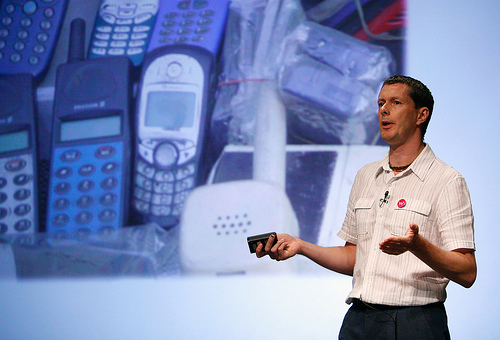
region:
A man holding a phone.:
[245, 73, 478, 338]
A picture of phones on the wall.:
[1, 2, 406, 279]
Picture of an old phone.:
[45, 17, 132, 249]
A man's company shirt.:
[336, 142, 476, 307]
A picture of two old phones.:
[44, 17, 218, 249]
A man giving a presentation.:
[246, 74, 478, 339]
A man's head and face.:
[376, 75, 434, 145]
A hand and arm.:
[377, 221, 478, 290]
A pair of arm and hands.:
[254, 220, 478, 289]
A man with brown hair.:
[254, 73, 478, 337]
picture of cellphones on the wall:
[36, 44, 326, 211]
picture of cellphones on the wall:
[11, 131, 223, 245]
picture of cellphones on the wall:
[119, 30, 319, 113]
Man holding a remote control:
[236, 228, 290, 261]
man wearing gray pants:
[334, 288, 450, 334]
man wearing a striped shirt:
[338, 143, 475, 295]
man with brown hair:
[374, 72, 431, 148]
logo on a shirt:
[391, 198, 406, 211]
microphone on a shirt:
[375, 183, 393, 213]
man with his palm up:
[354, 203, 429, 275]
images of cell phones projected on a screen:
[5, 3, 250, 257]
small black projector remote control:
[238, 219, 287, 265]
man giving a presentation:
[262, 61, 481, 337]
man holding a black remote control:
[245, 75, 483, 337]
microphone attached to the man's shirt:
[377, 188, 391, 208]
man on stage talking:
[225, 66, 491, 330]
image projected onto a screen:
[5, 6, 396, 258]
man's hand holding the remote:
[238, 227, 303, 272]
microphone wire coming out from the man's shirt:
[344, 291, 403, 329]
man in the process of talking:
[367, 72, 437, 150]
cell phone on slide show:
[127, 48, 205, 221]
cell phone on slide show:
[59, 82, 114, 251]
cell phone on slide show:
[181, 157, 293, 279]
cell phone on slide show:
[1, 87, 61, 239]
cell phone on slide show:
[11, 2, 41, 59]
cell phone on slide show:
[297, 32, 369, 103]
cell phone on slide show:
[220, 0, 270, 94]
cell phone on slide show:
[178, 2, 215, 36]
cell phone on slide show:
[96, 0, 149, 32]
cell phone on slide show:
[168, 10, 239, 40]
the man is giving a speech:
[274, 53, 494, 270]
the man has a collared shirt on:
[316, 135, 486, 329]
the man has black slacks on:
[337, 294, 449, 333]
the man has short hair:
[351, 63, 428, 133]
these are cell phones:
[32, 36, 200, 228]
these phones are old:
[22, 38, 209, 207]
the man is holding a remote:
[240, 230, 302, 258]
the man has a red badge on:
[395, 192, 418, 212]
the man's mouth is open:
[373, 114, 419, 144]